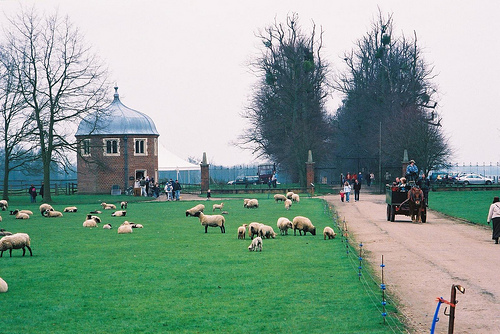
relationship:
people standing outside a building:
[129, 175, 183, 201] [75, 80, 163, 194]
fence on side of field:
[328, 202, 465, 332] [0, 193, 405, 332]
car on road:
[457, 172, 494, 188] [435, 185, 499, 189]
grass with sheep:
[2, 196, 400, 331] [195, 210, 227, 233]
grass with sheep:
[2, 196, 400, 331] [9, 208, 34, 220]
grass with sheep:
[2, 196, 400, 331] [294, 214, 317, 235]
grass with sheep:
[2, 196, 400, 331] [242, 195, 259, 207]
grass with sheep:
[2, 196, 400, 331] [81, 212, 101, 226]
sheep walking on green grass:
[194, 211, 226, 233] [22, 257, 348, 330]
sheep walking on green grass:
[248, 237, 262, 252] [246, 257, 336, 295]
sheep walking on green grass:
[36, 203, 56, 214] [35, 221, 76, 331]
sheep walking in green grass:
[0, 231, 32, 258] [11, 260, 162, 331]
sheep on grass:
[194, 211, 226, 233] [15, 189, 344, 321]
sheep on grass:
[239, 229, 275, 259] [25, 186, 357, 325]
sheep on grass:
[322, 224, 340, 244] [14, 196, 376, 322]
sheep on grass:
[115, 219, 138, 235] [12, 186, 373, 316]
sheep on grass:
[192, 209, 233, 236] [168, 196, 278, 266]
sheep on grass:
[272, 209, 297, 236] [161, 193, 350, 273]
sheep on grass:
[237, 193, 262, 209] [226, 193, 280, 222]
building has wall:
[75, 80, 163, 194] [84, 158, 120, 185]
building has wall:
[70, 80, 164, 194] [135, 156, 156, 168]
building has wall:
[70, 80, 164, 194] [75, 160, 98, 180]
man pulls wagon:
[406, 159, 420, 181] [379, 171, 435, 225]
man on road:
[401, 154, 421, 179] [344, 209, 460, 261]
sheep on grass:
[2, 189, 338, 254] [2, 196, 400, 331]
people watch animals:
[134, 175, 182, 201] [1, 189, 341, 263]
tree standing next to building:
[227, 8, 334, 184] [75, 80, 163, 194]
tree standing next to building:
[321, 4, 454, 188] [75, 80, 163, 194]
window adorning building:
[80, 139, 90, 156] [74, 78, 160, 195]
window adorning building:
[103, 139, 118, 154] [74, 78, 160, 195]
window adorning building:
[135, 140, 145, 154] [74, 78, 160, 195]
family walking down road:
[337, 175, 362, 203] [317, 181, 484, 331]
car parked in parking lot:
[449, 174, 494, 186] [419, 161, 483, 185]